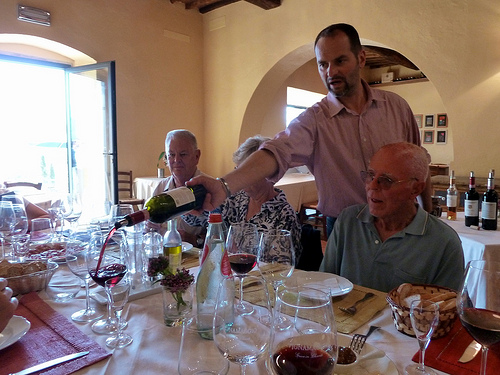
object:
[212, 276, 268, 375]
glass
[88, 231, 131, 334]
glass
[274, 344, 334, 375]
wine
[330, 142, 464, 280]
man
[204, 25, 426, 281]
man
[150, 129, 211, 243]
man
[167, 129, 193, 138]
hair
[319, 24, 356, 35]
hair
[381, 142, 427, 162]
hair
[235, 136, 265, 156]
hair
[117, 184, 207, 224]
bottle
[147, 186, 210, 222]
wine bottle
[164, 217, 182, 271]
bottles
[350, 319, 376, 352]
fork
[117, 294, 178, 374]
tablecloth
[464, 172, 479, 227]
bottle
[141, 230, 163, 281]
glass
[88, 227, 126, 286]
wine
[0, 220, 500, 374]
table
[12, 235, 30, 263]
glass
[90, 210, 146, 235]
wine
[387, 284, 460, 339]
basket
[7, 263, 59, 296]
basket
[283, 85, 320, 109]
sky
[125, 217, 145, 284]
glasses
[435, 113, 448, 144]
paintings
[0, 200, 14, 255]
glass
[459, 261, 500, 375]
glass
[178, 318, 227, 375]
glass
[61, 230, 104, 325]
wine glass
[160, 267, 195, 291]
flower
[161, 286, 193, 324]
glass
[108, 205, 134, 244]
glass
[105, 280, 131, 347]
glass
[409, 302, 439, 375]
glass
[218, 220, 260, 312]
glass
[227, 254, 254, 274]
wine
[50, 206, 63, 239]
glass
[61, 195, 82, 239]
glass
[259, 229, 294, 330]
glass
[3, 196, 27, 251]
glass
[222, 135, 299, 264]
someone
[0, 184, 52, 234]
someone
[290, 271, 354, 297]
plate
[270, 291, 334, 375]
glass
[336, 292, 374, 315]
fork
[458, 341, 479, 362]
utensil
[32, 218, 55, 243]
glass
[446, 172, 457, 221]
bottle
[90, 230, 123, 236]
rim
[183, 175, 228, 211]
hand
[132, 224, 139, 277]
sticks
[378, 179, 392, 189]
glasses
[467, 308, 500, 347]
wine